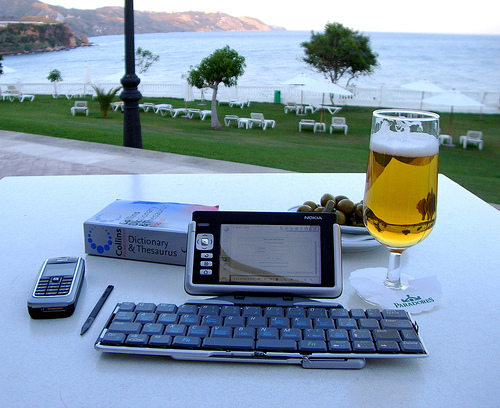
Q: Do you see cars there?
A: No, there are no cars.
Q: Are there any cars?
A: No, there are no cars.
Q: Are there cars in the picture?
A: No, there are no cars.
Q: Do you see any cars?
A: No, there are no cars.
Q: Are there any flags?
A: No, there are no flags.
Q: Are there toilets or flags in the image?
A: No, there are no flags or toilets.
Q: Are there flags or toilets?
A: No, there are no flags or toilets.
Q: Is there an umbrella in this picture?
A: Yes, there is an umbrella.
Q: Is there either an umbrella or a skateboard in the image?
A: Yes, there is an umbrella.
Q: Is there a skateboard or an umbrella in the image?
A: Yes, there is an umbrella.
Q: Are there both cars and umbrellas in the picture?
A: No, there is an umbrella but no cars.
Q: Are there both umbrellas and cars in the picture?
A: No, there is an umbrella but no cars.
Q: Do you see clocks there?
A: No, there are no clocks.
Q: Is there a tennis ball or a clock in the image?
A: No, there are no clocks or tennis balls.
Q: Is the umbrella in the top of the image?
A: Yes, the umbrella is in the top of the image.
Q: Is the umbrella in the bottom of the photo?
A: No, the umbrella is in the top of the image.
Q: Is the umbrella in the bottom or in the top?
A: The umbrella is in the top of the image.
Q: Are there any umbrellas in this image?
A: Yes, there is an umbrella.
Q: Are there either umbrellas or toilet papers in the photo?
A: Yes, there is an umbrella.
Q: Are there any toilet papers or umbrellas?
A: Yes, there is an umbrella.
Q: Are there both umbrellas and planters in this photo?
A: No, there is an umbrella but no planters.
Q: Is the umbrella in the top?
A: Yes, the umbrella is in the top of the image.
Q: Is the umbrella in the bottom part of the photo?
A: No, the umbrella is in the top of the image.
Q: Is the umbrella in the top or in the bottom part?
A: The umbrella is in the top of the image.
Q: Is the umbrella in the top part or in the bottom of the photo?
A: The umbrella is in the top of the image.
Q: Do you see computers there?
A: Yes, there is a computer.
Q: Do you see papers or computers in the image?
A: Yes, there is a computer.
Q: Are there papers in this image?
A: No, there are no papers.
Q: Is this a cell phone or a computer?
A: This is a computer.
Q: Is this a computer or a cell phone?
A: This is a computer.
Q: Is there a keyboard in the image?
A: Yes, there is a keyboard.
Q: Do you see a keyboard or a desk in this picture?
A: Yes, there is a keyboard.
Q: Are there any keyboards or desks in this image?
A: Yes, there is a keyboard.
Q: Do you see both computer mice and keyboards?
A: No, there is a keyboard but no computer mice.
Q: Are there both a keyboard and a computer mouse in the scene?
A: No, there is a keyboard but no computer mice.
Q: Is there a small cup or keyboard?
A: Yes, there is a small keyboard.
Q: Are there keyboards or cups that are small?
A: Yes, the keyboard is small.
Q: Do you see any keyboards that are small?
A: Yes, there is a small keyboard.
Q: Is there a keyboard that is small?
A: Yes, there is a keyboard that is small.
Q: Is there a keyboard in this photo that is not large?
A: Yes, there is a small keyboard.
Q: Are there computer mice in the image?
A: No, there are no computer mice.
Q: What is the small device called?
A: The device is a keyboard.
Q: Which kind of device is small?
A: The device is a keyboard.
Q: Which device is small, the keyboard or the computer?
A: The keyboard is small.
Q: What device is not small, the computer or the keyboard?
A: The computer is not small.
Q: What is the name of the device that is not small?
A: The device is a computer.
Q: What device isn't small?
A: The device is a computer.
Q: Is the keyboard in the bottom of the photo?
A: Yes, the keyboard is in the bottom of the image.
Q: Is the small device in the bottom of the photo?
A: Yes, the keyboard is in the bottom of the image.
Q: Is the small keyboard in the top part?
A: No, the keyboard is in the bottom of the image.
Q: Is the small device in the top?
A: No, the keyboard is in the bottom of the image.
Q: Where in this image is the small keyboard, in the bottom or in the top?
A: The keyboard is in the bottom of the image.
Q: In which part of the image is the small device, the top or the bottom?
A: The keyboard is in the bottom of the image.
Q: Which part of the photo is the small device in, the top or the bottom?
A: The keyboard is in the bottom of the image.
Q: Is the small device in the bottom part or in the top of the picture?
A: The keyboard is in the bottom of the image.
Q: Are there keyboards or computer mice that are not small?
A: No, there is a keyboard but it is small.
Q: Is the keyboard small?
A: Yes, the keyboard is small.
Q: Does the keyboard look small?
A: Yes, the keyboard is small.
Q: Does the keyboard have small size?
A: Yes, the keyboard is small.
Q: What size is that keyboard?
A: The keyboard is small.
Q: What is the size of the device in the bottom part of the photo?
A: The keyboard is small.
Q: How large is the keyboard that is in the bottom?
A: The keyboard is small.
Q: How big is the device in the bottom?
A: The keyboard is small.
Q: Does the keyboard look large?
A: No, the keyboard is small.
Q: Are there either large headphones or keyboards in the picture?
A: No, there is a keyboard but it is small.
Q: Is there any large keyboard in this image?
A: No, there is a keyboard but it is small.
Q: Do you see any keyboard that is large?
A: No, there is a keyboard but it is small.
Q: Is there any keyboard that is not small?
A: No, there is a keyboard but it is small.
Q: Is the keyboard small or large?
A: The keyboard is small.